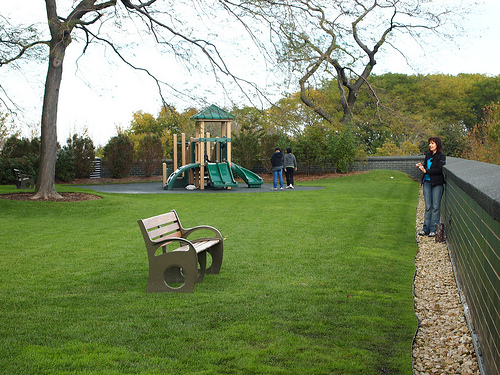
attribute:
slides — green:
[163, 160, 265, 190]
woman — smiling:
[416, 136, 448, 238]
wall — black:
[350, 154, 495, 374]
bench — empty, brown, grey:
[138, 208, 224, 298]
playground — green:
[192, 102, 237, 121]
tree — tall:
[1, 1, 191, 204]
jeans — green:
[270, 168, 287, 190]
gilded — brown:
[161, 118, 234, 189]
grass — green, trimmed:
[2, 169, 415, 370]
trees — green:
[2, 106, 367, 192]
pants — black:
[285, 167, 296, 188]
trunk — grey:
[36, 44, 65, 207]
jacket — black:
[419, 153, 450, 186]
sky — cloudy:
[0, 1, 495, 151]